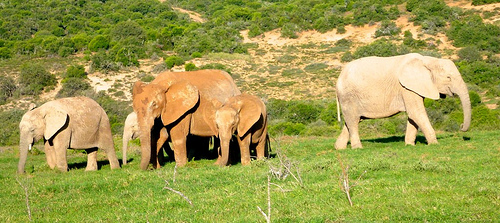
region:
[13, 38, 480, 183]
elephants in a herd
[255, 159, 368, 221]
bushes without leaves in grass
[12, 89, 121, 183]
elephant with small tusks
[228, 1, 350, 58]
green shrubbery in dirt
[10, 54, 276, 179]
elephants of different sizes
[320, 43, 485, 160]
elephant walking in green grass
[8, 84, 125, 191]
elephant with trunk on ground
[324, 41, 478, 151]
elephant and its shadow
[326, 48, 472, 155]
elephant that looks like it is smiling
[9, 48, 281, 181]
group of four elephants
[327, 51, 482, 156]
gray elephant standing in a field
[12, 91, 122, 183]
gray elephant standing in a field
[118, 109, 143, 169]
gray elephant standing in a field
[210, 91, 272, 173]
gray elephant standing in a field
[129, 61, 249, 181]
gray elephant standing in a field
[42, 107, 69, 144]
large ear of an elephant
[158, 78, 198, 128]
large ear of an elephant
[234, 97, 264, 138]
large ear of an elephant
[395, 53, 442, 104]
large ear of an elephant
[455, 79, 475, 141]
large trunk of an elephant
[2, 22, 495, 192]
a herd of elephants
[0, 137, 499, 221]
green grass on the ground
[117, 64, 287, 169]
baby elephant standing next to an adult elephant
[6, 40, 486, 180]
elephants standing in the grass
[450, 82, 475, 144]
bottom of the trunk is curled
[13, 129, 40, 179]
trunk hanging down to the ground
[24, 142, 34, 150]
small white tusk on the side of the trunk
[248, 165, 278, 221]
stick jutting out of the ground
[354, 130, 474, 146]
shadow on the ground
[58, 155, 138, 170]
shadow from the elephant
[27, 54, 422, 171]
elephants in the grass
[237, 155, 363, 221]
small branches in grass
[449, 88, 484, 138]
trunk of the elephant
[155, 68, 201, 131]
ear of the elephant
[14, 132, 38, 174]
trunk of the elephant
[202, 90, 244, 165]
head of the elephant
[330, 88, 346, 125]
tail of the elephant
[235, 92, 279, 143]
ear of the elephant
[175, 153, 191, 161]
foot of the elephant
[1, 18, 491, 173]
a herd of elephants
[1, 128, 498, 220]
green grass on the ground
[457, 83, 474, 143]
bottom of the trunk is curled under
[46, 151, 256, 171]
shadows on the ground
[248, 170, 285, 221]
stick jutting out of the ground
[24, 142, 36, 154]
small white tusk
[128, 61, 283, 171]
baby elephant standing by an adult elephant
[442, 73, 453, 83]
eye on the side of the head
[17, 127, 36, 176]
trunk hanging down to the ground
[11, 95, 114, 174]
a grey elephant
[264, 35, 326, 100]
patches of grass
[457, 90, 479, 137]
the elephants trunk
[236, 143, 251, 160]
the elephants leg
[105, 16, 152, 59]
the bushes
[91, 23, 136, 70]
the bushes are green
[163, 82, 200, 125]
Ear of a elephant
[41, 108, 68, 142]
Ear of a elephant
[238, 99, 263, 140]
Ear of a elephant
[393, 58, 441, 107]
Ear of a elephant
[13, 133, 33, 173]
Trunk of an elephant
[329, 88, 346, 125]
Tail of an elephant